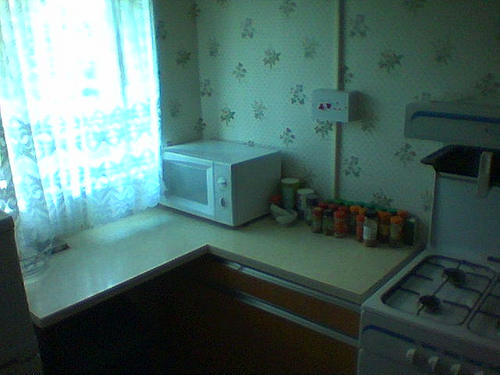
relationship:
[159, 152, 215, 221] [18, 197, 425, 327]
microwave door on counter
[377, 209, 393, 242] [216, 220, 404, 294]
spice on counter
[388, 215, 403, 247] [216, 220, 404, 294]
spice on counter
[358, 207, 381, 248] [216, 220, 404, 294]
spice on counter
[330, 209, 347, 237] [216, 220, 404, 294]
spice on counter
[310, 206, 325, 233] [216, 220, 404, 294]
spice on counter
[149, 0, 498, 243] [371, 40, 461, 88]
wallpaper oncovering wall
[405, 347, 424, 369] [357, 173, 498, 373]
knob on stove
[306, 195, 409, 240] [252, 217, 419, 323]
spices on top of counter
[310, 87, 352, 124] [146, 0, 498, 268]
switch on wall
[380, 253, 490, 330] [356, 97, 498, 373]
burner on stove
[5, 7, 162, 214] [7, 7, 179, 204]
white curtain on window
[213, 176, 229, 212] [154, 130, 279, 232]
knobs on microwave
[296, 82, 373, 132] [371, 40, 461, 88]
box on wall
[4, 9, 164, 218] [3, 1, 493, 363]
curtain in kitchen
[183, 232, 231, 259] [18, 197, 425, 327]
corner on counter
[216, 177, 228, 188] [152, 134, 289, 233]
knobs on microwave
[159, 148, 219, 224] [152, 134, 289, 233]
microwave door on microwave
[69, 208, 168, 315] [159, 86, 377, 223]
reflection on counter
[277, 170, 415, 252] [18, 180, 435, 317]
spices on counter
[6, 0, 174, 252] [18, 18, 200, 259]
sheers in window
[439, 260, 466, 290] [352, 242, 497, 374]
gas burner on stove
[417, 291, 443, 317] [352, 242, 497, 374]
gas burner on stove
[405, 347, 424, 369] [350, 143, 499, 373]
knob on stove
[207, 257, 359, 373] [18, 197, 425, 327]
cabinet below counter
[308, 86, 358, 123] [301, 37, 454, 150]
outlet on wall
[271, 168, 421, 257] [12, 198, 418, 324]
bottles on countertop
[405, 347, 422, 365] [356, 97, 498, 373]
knob on stove